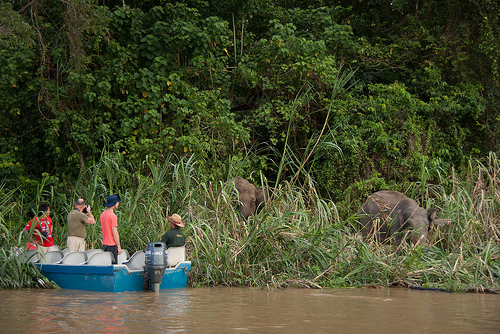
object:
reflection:
[33, 290, 164, 323]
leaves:
[147, 109, 163, 119]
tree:
[4, 10, 42, 187]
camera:
[37, 227, 51, 241]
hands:
[30, 239, 39, 245]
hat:
[164, 213, 187, 228]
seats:
[84, 249, 118, 264]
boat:
[25, 262, 193, 291]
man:
[99, 194, 126, 264]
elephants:
[226, 176, 268, 223]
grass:
[0, 137, 500, 291]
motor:
[144, 240, 171, 286]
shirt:
[65, 211, 92, 239]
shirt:
[159, 227, 188, 250]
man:
[156, 211, 188, 253]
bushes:
[2, 100, 499, 290]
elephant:
[357, 189, 438, 254]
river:
[0, 271, 500, 334]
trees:
[89, 77, 252, 185]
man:
[65, 197, 96, 255]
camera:
[79, 202, 90, 214]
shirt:
[26, 216, 59, 251]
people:
[24, 201, 60, 262]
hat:
[101, 195, 124, 207]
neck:
[35, 217, 47, 221]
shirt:
[97, 208, 120, 247]